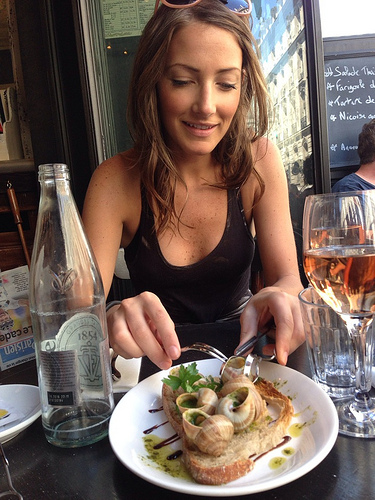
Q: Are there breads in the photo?
A: Yes, there is a bread.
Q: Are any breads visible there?
A: Yes, there is a bread.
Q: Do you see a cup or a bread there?
A: Yes, there is a bread.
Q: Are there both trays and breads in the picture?
A: No, there is a bread but no trays.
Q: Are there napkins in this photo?
A: No, there are no napkins.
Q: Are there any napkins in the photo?
A: No, there are no napkins.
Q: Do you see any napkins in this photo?
A: No, there are no napkins.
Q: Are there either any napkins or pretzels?
A: No, there are no napkins or pretzels.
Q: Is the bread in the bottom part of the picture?
A: Yes, the bread is in the bottom of the image.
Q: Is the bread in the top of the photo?
A: No, the bread is in the bottom of the image.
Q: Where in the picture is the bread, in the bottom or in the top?
A: The bread is in the bottom of the image.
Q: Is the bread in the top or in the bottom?
A: The bread is in the bottom of the image.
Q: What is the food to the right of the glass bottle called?
A: The food is a bread.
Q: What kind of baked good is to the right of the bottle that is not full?
A: The food is a bread.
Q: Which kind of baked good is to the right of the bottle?
A: The food is a bread.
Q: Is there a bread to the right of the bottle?
A: Yes, there is a bread to the right of the bottle.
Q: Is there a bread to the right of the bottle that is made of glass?
A: Yes, there is a bread to the right of the bottle.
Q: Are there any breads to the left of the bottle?
A: No, the bread is to the right of the bottle.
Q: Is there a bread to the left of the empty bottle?
A: No, the bread is to the right of the bottle.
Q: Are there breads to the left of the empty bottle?
A: No, the bread is to the right of the bottle.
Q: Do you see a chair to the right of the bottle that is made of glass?
A: No, there is a bread to the right of the bottle.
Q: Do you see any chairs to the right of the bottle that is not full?
A: No, there is a bread to the right of the bottle.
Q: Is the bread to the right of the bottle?
A: Yes, the bread is to the right of the bottle.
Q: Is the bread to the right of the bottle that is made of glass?
A: Yes, the bread is to the right of the bottle.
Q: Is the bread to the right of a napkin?
A: No, the bread is to the right of the bottle.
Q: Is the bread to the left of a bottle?
A: No, the bread is to the right of a bottle.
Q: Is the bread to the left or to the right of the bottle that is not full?
A: The bread is to the right of the bottle.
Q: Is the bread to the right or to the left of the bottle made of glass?
A: The bread is to the right of the bottle.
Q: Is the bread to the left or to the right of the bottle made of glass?
A: The bread is to the right of the bottle.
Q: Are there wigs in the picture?
A: No, there are no wigs.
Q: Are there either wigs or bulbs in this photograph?
A: No, there are no wigs or bulbs.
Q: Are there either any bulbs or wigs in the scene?
A: No, there are no wigs or bulbs.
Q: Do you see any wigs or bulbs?
A: No, there are no wigs or bulbs.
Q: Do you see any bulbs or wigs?
A: No, there are no wigs or bulbs.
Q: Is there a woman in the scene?
A: Yes, there is a woman.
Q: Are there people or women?
A: Yes, there is a woman.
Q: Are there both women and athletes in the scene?
A: No, there is a woman but no athletes.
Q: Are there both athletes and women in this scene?
A: No, there is a woman but no athletes.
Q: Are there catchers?
A: No, there are no catchers.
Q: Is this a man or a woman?
A: This is a woman.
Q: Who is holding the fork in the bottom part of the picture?
A: The woman is holding the fork.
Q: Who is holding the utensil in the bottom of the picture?
A: The woman is holding the fork.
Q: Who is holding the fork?
A: The woman is holding the fork.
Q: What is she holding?
A: The woman is holding the fork.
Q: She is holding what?
A: The woman is holding the fork.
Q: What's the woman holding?
A: The woman is holding the fork.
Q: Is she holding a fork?
A: Yes, the woman is holding a fork.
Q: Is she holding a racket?
A: No, the woman is holding a fork.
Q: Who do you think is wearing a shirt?
A: The woman is wearing a shirt.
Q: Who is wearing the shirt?
A: The woman is wearing a shirt.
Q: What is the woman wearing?
A: The woman is wearing a shirt.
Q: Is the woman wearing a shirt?
A: Yes, the woman is wearing a shirt.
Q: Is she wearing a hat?
A: No, the woman is wearing a shirt.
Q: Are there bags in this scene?
A: No, there are no bags.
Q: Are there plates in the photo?
A: Yes, there is a plate.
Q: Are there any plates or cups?
A: Yes, there is a plate.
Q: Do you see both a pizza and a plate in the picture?
A: No, there is a plate but no pizzas.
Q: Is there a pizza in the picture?
A: No, there are no pizzas.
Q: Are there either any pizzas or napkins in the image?
A: No, there are no pizzas or napkins.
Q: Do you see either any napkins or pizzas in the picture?
A: No, there are no pizzas or napkins.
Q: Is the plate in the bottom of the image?
A: Yes, the plate is in the bottom of the image.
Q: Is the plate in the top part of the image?
A: No, the plate is in the bottom of the image.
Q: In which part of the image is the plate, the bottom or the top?
A: The plate is in the bottom of the image.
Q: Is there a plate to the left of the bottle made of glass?
A: Yes, there is a plate to the left of the bottle.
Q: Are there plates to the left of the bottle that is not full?
A: Yes, there is a plate to the left of the bottle.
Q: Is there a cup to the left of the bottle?
A: No, there is a plate to the left of the bottle.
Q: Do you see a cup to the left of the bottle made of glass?
A: No, there is a plate to the left of the bottle.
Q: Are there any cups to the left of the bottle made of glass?
A: No, there is a plate to the left of the bottle.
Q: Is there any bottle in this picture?
A: Yes, there is a bottle.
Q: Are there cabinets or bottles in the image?
A: Yes, there is a bottle.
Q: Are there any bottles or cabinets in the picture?
A: Yes, there is a bottle.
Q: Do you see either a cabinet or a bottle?
A: Yes, there is a bottle.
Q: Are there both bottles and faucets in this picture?
A: No, there is a bottle but no faucets.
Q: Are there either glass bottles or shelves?
A: Yes, there is a glass bottle.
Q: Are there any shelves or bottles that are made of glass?
A: Yes, the bottle is made of glass.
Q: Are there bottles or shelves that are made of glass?
A: Yes, the bottle is made of glass.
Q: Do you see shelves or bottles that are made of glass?
A: Yes, the bottle is made of glass.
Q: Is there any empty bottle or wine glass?
A: Yes, there is an empty bottle.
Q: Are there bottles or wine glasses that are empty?
A: Yes, the bottle is empty.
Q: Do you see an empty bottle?
A: Yes, there is an empty bottle.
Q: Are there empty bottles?
A: Yes, there is an empty bottle.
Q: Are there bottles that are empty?
A: Yes, there is a bottle that is empty.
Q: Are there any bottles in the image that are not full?
A: Yes, there is a empty bottle.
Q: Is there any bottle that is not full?
A: Yes, there is a empty bottle.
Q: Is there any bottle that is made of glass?
A: Yes, there is a bottle that is made of glass.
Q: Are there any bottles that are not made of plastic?
A: Yes, there is a bottle that is made of glass.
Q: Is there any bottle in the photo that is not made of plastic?
A: Yes, there is a bottle that is made of glass.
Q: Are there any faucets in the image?
A: No, there are no faucets.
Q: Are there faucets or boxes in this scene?
A: No, there are no faucets or boxes.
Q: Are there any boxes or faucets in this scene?
A: No, there are no faucets or boxes.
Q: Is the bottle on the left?
A: Yes, the bottle is on the left of the image.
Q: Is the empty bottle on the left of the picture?
A: Yes, the bottle is on the left of the image.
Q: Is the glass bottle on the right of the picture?
A: No, the bottle is on the left of the image.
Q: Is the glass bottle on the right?
A: No, the bottle is on the left of the image.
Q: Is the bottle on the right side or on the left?
A: The bottle is on the left of the image.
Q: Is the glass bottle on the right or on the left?
A: The bottle is on the left of the image.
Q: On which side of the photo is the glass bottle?
A: The bottle is on the left of the image.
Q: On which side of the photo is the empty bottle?
A: The bottle is on the left of the image.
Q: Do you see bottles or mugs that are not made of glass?
A: No, there is a bottle but it is made of glass.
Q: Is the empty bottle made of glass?
A: Yes, the bottle is made of glass.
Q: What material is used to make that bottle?
A: The bottle is made of glass.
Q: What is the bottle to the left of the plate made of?
A: The bottle is made of glass.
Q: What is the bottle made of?
A: The bottle is made of glass.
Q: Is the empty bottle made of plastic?
A: No, the bottle is made of glass.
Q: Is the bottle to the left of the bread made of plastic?
A: No, the bottle is made of glass.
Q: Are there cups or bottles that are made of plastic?
A: No, there is a bottle but it is made of glass.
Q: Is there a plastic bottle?
A: No, there is a bottle but it is made of glass.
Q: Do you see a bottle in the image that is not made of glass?
A: No, there is a bottle but it is made of glass.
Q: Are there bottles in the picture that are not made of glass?
A: No, there is a bottle but it is made of glass.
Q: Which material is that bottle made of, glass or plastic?
A: The bottle is made of glass.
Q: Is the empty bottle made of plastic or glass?
A: The bottle is made of glass.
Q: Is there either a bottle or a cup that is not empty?
A: No, there is a bottle but it is empty.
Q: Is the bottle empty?
A: Yes, the bottle is empty.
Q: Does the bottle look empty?
A: Yes, the bottle is empty.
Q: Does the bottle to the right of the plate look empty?
A: Yes, the bottle is empty.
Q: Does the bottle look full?
A: No, the bottle is empty.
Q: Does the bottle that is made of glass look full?
A: No, the bottle is empty.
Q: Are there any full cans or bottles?
A: No, there is a bottle but it is empty.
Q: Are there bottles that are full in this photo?
A: No, there is a bottle but it is empty.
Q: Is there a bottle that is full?
A: No, there is a bottle but it is empty.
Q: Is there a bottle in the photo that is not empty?
A: No, there is a bottle but it is empty.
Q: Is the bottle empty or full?
A: The bottle is empty.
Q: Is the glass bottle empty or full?
A: The bottle is empty.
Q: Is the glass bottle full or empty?
A: The bottle is empty.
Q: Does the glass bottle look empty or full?
A: The bottle is empty.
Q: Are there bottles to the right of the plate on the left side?
A: Yes, there is a bottle to the right of the plate.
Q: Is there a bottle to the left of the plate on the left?
A: No, the bottle is to the right of the plate.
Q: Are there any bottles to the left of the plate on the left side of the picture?
A: No, the bottle is to the right of the plate.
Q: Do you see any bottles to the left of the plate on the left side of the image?
A: No, the bottle is to the right of the plate.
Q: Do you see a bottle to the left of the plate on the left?
A: No, the bottle is to the right of the plate.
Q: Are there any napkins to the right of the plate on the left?
A: No, there is a bottle to the right of the plate.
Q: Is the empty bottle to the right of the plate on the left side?
A: Yes, the bottle is to the right of the plate.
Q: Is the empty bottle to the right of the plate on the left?
A: Yes, the bottle is to the right of the plate.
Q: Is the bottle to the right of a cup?
A: No, the bottle is to the right of the plate.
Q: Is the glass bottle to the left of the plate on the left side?
A: No, the bottle is to the right of the plate.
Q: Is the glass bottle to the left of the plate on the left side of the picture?
A: No, the bottle is to the right of the plate.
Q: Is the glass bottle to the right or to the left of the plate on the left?
A: The bottle is to the right of the plate.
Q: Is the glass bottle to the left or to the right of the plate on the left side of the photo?
A: The bottle is to the right of the plate.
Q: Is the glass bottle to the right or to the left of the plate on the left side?
A: The bottle is to the right of the plate.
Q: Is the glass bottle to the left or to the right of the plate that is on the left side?
A: The bottle is to the right of the plate.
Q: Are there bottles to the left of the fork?
A: Yes, there is a bottle to the left of the fork.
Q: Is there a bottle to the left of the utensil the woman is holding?
A: Yes, there is a bottle to the left of the fork.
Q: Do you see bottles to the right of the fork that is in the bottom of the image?
A: No, the bottle is to the left of the fork.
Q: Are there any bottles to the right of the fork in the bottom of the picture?
A: No, the bottle is to the left of the fork.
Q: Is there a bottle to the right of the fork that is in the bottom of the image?
A: No, the bottle is to the left of the fork.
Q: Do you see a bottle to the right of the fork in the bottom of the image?
A: No, the bottle is to the left of the fork.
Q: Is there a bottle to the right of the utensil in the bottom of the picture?
A: No, the bottle is to the left of the fork.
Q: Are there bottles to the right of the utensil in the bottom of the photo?
A: No, the bottle is to the left of the fork.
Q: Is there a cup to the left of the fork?
A: No, there is a bottle to the left of the fork.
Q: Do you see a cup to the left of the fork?
A: No, there is a bottle to the left of the fork.